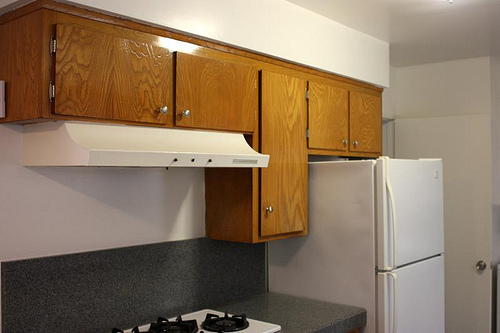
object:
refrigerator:
[263, 151, 448, 331]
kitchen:
[1, 2, 498, 331]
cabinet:
[205, 54, 309, 244]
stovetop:
[98, 308, 286, 331]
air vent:
[380, 116, 396, 160]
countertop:
[221, 292, 366, 331]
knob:
[158, 104, 169, 114]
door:
[391, 110, 493, 332]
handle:
[374, 155, 398, 273]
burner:
[198, 310, 251, 333]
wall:
[2, 124, 207, 263]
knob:
[266, 205, 274, 214]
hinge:
[305, 89, 311, 100]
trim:
[2, 236, 269, 332]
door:
[376, 156, 446, 272]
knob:
[475, 259, 487, 270]